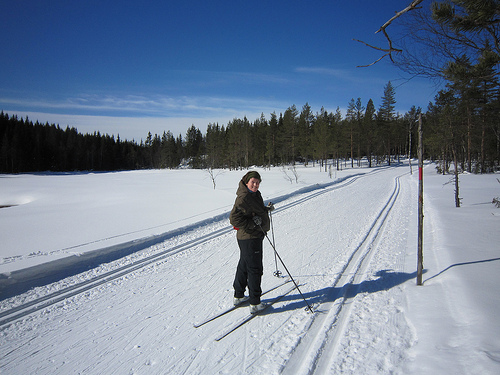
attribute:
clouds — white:
[2, 65, 424, 147]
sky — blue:
[2, 1, 497, 146]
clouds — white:
[70, 31, 233, 126]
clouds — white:
[95, 93, 205, 133]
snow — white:
[83, 257, 123, 309]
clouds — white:
[153, 81, 225, 101]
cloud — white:
[296, 64, 358, 81]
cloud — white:
[181, 60, 289, 85]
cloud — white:
[5, 92, 157, 112]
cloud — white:
[73, 87, 291, 112]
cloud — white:
[303, 105, 408, 118]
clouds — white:
[107, 80, 157, 137]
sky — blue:
[41, 8, 323, 129]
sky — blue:
[193, 2, 282, 76]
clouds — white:
[212, 0, 276, 60]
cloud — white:
[20, 96, 372, 148]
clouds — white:
[208, 56, 298, 108]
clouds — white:
[272, 44, 382, 115]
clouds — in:
[271, 39, 348, 93]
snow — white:
[6, 152, 498, 368]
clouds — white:
[68, 88, 175, 120]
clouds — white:
[162, 60, 363, 99]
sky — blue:
[4, 3, 437, 104]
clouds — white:
[127, 112, 183, 139]